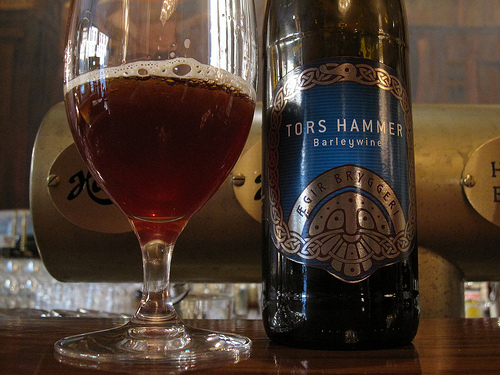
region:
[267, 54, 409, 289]
Blue and silver label on a bottle.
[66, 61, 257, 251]
Wine in a glass.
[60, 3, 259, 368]
A clear wine glass.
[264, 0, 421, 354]
Bottle of barleywine.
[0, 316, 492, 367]
Shiny wood counter top.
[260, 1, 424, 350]
A dark bottle with a label on it.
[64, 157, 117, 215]
Black lettering on a pipe.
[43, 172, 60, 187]
A screw with a line in it.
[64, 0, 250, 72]
Reflections on the wine glass.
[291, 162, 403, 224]
Foreign writing on a label.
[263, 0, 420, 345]
the label is on the bottle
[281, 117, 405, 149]
the lettering is white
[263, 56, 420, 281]
the label is blue gold and black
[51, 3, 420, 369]
the glass is beside the bottle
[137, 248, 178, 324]
the stem is clear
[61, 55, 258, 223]
the bubbles are on top of the drink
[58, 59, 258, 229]
the drink is brown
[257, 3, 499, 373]
the bottle is on the table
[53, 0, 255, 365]
the glass is on the table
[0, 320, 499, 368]
the table is brown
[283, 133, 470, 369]
a bottle of alcohol on the table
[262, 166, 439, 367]
a table with a bottle of bear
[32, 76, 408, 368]
glass and bottle on table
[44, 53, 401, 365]
a glass and bottle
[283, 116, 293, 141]
white letter on bottle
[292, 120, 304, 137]
white letter on bottle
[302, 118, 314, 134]
white letter on bottle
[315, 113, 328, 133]
white letter on bottle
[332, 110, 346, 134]
white letter on bottle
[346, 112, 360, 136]
white letter on bottle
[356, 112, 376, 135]
white letter on bottle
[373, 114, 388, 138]
white letter on bottle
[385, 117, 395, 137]
white letter on bottle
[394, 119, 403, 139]
white letter on bottle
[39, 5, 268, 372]
a glass with wine in it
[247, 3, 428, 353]
a bottle of wine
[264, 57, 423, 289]
a blue and gold label on the bottle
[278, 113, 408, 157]
white letters on the label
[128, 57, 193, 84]
bubbles in the wine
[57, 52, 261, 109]
foam on the wine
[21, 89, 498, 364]
brown object behind glass and bottle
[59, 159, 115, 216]
the letter h beside the wine glass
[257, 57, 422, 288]
gold trim on label on wine bottle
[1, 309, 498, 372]
a brown table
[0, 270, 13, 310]
glass on the wood counter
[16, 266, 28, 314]
glass on the wood counter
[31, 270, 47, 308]
glass on the wood counter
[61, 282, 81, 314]
glass on the wood counter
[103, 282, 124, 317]
glass on the wood counter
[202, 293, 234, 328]
glass on the wood counter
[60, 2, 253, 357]
a glass on the table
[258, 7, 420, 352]
a bottle on the table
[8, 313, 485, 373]
a wooden table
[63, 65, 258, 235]
beer in the glass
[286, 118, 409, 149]
writing on the bottle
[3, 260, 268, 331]
glasses in the distance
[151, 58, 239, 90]
bubbles of the beer